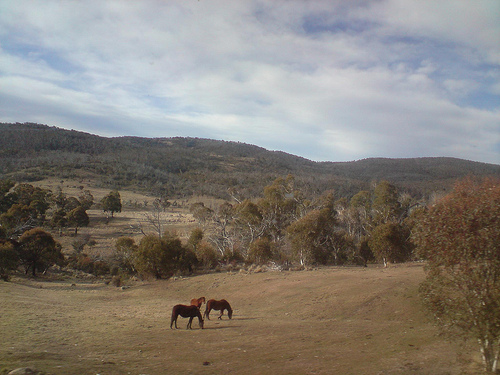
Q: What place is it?
A: It is a field.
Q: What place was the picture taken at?
A: It was taken at the field.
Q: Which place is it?
A: It is a field.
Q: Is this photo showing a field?
A: Yes, it is showing a field.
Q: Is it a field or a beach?
A: It is a field.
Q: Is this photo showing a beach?
A: No, the picture is showing a field.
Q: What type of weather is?
A: It is cloudy.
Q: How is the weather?
A: It is cloudy.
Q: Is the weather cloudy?
A: Yes, it is cloudy.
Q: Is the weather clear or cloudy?
A: It is cloudy.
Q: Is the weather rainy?
A: No, it is cloudy.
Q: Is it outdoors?
A: Yes, it is outdoors.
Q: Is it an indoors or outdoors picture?
A: It is outdoors.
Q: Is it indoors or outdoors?
A: It is outdoors.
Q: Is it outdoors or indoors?
A: It is outdoors.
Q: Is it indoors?
A: No, it is outdoors.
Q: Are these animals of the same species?
A: Yes, all the animals are horses.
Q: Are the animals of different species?
A: No, all the animals are horses.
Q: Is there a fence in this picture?
A: No, there are no fences.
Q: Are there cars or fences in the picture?
A: No, there are no fences or cars.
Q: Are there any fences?
A: No, there are no fences.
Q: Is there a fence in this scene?
A: No, there are no fences.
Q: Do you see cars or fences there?
A: No, there are no fences or cars.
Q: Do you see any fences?
A: No, there are no fences.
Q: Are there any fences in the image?
A: No, there are no fences.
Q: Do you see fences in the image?
A: No, there are no fences.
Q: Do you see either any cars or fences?
A: No, there are no fences or cars.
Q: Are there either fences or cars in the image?
A: No, there are no fences or cars.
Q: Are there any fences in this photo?
A: No, there are no fences.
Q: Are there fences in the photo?
A: No, there are no fences.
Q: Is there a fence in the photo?
A: No, there are no fences.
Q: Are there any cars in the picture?
A: No, there are no cars.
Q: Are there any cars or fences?
A: No, there are no cars or fences.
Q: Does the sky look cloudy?
A: Yes, the sky is cloudy.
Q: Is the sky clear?
A: No, the sky is cloudy.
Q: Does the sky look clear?
A: No, the sky is cloudy.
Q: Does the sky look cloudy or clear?
A: The sky is cloudy.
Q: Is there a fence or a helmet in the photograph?
A: No, there are no fences or helmets.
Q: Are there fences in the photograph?
A: No, there are no fences.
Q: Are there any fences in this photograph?
A: No, there are no fences.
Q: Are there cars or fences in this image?
A: No, there are no fences or cars.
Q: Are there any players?
A: No, there are no players.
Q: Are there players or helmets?
A: No, there are no players or helmets.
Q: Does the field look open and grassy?
A: Yes, the field is open and grassy.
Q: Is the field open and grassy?
A: Yes, the field is open and grassy.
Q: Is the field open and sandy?
A: No, the field is open but grassy.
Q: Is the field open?
A: Yes, the field is open.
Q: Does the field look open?
A: Yes, the field is open.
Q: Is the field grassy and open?
A: Yes, the field is grassy and open.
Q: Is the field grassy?
A: Yes, the field is grassy.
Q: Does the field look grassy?
A: Yes, the field is grassy.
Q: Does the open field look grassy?
A: Yes, the field is grassy.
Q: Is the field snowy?
A: No, the field is grassy.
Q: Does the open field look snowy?
A: No, the field is grassy.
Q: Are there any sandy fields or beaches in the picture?
A: No, there is a field but it is grassy.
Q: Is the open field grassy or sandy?
A: The field is grassy.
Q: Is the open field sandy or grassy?
A: The field is grassy.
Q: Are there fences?
A: No, there are no fences.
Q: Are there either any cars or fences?
A: No, there are no fences or cars.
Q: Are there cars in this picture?
A: No, there are no cars.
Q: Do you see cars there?
A: No, there are no cars.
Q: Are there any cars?
A: No, there are no cars.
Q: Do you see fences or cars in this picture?
A: No, there are no cars or fences.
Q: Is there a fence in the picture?
A: No, there are no fences.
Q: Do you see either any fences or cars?
A: No, there are no fences or cars.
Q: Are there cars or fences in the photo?
A: No, there are no fences or cars.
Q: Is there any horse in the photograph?
A: Yes, there is a horse.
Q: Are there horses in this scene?
A: Yes, there is a horse.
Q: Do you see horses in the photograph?
A: Yes, there is a horse.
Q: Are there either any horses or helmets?
A: Yes, there is a horse.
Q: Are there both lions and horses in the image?
A: No, there is a horse but no lions.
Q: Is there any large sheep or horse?
A: Yes, there is a large horse.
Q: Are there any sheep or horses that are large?
A: Yes, the horse is large.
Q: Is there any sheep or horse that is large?
A: Yes, the horse is large.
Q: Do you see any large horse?
A: Yes, there is a large horse.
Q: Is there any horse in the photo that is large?
A: Yes, there is a horse that is large.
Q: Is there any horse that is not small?
A: Yes, there is a large horse.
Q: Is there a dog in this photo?
A: No, there are no dogs.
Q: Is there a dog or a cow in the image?
A: No, there are no dogs or cows.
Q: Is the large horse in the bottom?
A: Yes, the horse is in the bottom of the image.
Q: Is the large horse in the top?
A: No, the horse is in the bottom of the image.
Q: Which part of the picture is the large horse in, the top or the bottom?
A: The horse is in the bottom of the image.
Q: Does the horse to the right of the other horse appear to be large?
A: Yes, the horse is large.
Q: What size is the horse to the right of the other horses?
A: The horse is large.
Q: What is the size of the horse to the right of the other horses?
A: The horse is large.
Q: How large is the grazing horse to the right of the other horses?
A: The horse is large.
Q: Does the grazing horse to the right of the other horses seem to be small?
A: No, the horse is large.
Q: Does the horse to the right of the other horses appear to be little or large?
A: The horse is large.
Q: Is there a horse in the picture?
A: Yes, there are horses.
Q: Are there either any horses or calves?
A: Yes, there are horses.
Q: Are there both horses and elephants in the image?
A: No, there are horses but no elephants.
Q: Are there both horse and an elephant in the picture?
A: No, there are horses but no elephants.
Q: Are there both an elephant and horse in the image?
A: No, there are horses but no elephants.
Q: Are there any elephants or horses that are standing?
A: Yes, the horses are standing.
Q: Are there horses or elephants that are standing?
A: Yes, the horses are standing.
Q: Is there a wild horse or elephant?
A: Yes, there are wild horses.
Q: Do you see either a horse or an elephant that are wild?
A: Yes, the horses are wild.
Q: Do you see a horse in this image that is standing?
A: Yes, there are horses that are standing.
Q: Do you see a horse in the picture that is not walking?
A: Yes, there are horses that are standing .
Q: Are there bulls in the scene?
A: No, there are no bulls.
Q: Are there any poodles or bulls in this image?
A: No, there are no bulls or poodles.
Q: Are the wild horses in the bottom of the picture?
A: Yes, the horses are in the bottom of the image.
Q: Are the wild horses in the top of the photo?
A: No, the horses are in the bottom of the image.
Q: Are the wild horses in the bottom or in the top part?
A: The horses are in the bottom of the image.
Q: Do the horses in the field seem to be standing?
A: Yes, the horses are standing.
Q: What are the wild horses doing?
A: The horses are standing.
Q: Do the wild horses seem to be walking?
A: No, the horses are standing.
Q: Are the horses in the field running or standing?
A: The horses are standing.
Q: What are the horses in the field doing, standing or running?
A: The horses are standing.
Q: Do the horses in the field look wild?
A: Yes, the horses are wild.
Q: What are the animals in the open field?
A: The animals are horses.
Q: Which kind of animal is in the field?
A: The animals are horses.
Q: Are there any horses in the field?
A: Yes, there are horses in the field.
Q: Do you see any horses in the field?
A: Yes, there are horses in the field.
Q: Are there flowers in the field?
A: No, there are horses in the field.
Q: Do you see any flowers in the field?
A: No, there are horses in the field.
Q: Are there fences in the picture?
A: No, there are no fences.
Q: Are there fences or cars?
A: No, there are no fences or cars.